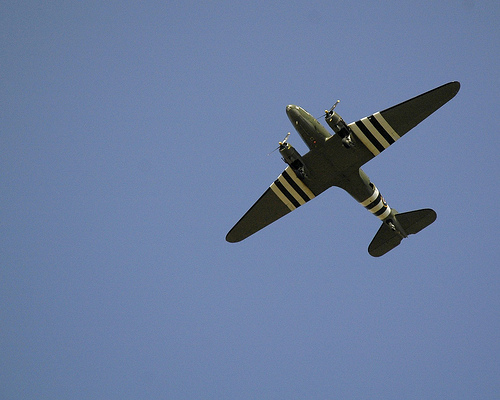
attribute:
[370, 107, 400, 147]
stripe — white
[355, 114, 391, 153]
stripe — white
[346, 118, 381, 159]
stripe — white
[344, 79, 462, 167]
wing — plane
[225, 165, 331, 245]
wing — plane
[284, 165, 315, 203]
stripe — white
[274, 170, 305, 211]
stripe — white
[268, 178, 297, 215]
stripe — white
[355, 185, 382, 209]
stripe — white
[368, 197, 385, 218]
stripe — white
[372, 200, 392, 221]
stripe — white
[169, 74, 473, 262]
plane — green, white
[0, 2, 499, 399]
sky — open, clear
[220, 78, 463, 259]
airplane — flying, small, green, white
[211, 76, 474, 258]
plane — black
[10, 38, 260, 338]
sky — blue, cloudless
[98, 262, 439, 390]
sky — cloudless, blue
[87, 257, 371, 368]
sky — blue, cloudless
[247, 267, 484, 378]
sky — cloudless, blue